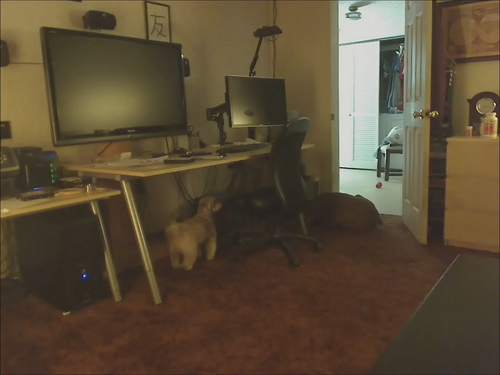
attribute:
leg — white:
[181, 245, 196, 272]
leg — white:
[168, 253, 181, 270]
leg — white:
[201, 237, 215, 259]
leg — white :
[203, 234, 218, 261]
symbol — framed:
[145, 1, 175, 41]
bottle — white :
[475, 103, 497, 138]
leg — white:
[165, 248, 181, 270]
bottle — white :
[463, 122, 478, 136]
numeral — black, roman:
[223, 70, 295, 130]